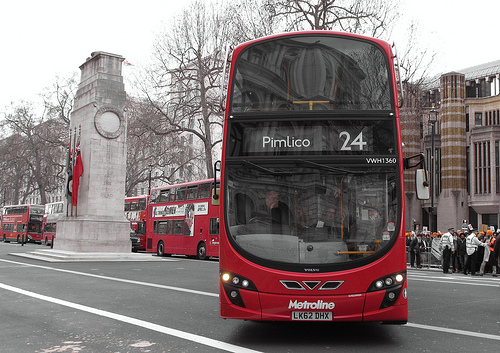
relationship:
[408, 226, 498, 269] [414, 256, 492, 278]
people standing on sidewalk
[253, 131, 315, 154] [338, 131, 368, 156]
letters and numbers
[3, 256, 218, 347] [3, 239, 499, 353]
lines on street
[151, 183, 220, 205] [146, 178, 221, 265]
upper deck on bus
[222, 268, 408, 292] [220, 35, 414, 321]
headlights on a bus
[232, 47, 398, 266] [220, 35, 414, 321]
windshield on bus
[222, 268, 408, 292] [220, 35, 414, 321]
headlights on bus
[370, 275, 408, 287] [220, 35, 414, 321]
headlight on bus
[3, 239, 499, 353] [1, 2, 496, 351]
street in city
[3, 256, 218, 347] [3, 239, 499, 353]
lines painted on street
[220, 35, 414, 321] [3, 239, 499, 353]
bus on street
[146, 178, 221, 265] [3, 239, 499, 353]
bus on street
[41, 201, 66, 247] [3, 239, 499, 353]
passenger bus on street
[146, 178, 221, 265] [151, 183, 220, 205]
bus with a upper deck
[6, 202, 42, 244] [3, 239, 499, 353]
bus on street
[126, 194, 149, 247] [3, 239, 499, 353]
bus on street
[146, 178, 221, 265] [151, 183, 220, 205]
bus with an upper deck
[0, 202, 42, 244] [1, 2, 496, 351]
bus are city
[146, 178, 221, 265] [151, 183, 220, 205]
bus has an upper deck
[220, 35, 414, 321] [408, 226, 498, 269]
commuter bus for people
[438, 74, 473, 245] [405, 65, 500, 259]
pillar on building